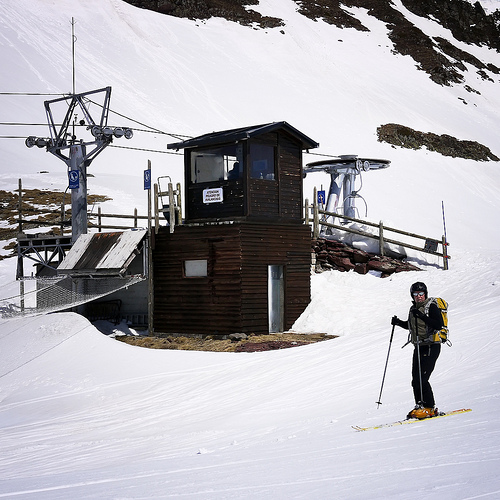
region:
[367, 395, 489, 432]
Two Orange skis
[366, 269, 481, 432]
Person standing on snow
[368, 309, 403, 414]
Ski pole holding by a person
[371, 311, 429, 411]
Two ski poles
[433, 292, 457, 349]
Yellow backpack carried by a skier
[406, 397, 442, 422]
Orange ski boots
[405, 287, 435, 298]
Person wearing googles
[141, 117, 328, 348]
Wooden stand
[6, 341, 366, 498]
Field covered with snow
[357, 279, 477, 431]
Skier with yellow backpack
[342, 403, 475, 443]
The skier's yellow skis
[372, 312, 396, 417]
Pole the skier is holding in his right hand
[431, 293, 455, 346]
Yellow backpack on the skier's back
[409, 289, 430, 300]
Goggles on the skier's face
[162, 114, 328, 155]
Roof of the log structure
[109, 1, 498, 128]
Snow covered mountain in the background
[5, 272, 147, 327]
White netting to the left of the brown log structure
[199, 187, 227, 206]
Small white sign on the second story of the log structure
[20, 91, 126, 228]
Support for the ski lift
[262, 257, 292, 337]
Entrance way on the first story of the log structure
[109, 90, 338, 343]
A ski house.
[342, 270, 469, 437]
A skier moving down a mountainside.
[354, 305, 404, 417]
A pole for skiing.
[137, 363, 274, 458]
A white snow covered ground.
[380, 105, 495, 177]
A rock out crop on a mountainside.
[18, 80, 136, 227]
A ski lift support structure.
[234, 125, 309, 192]
A window used to view skiers.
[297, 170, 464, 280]
A ski lift off ramp.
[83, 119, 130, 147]
A set of rollers to support ski cable.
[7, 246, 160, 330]
A large net.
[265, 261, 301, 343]
large white side door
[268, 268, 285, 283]
glass partition in white side door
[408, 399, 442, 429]
orange and white snow shoes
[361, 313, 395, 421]
long thin ski poles with tip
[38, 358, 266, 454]
smooth white snow surface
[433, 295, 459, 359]
man carrying yellow backpack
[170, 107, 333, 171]
black roof on small building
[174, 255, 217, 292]
small white square on brown building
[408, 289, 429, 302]
man wearing shiny gray goggles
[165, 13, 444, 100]
snow covered mountain range